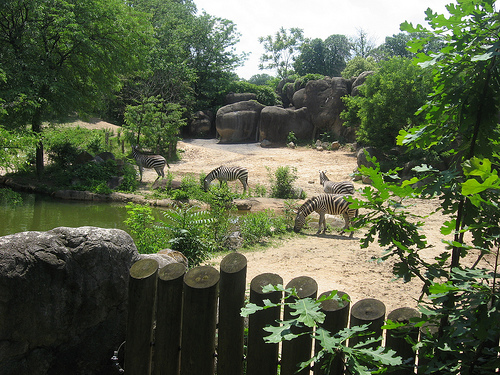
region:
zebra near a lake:
[277, 185, 357, 232]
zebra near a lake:
[310, 171, 340, 191]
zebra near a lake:
[196, 162, 257, 200]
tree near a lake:
[20, 70, 67, 161]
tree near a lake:
[128, 86, 182, 139]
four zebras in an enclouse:
[129, 136, 364, 238]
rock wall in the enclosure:
[185, 59, 375, 138]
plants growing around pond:
[13, 127, 276, 261]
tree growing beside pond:
[2, 32, 188, 172]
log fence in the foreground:
[135, 254, 476, 373]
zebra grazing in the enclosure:
[195, 159, 362, 232]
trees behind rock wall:
[196, 36, 413, 113]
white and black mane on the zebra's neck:
[294, 197, 312, 212]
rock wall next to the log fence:
[6, 222, 131, 359]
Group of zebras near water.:
[123, 146, 368, 249]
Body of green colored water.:
[9, 175, 326, 255]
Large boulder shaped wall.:
[222, 67, 358, 147]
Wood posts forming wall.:
[124, 241, 315, 373]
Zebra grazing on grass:
[284, 191, 371, 243]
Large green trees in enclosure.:
[1, 0, 235, 166]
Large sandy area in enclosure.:
[162, 120, 496, 315]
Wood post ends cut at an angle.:
[115, 233, 286, 333]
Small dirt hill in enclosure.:
[4, 68, 238, 184]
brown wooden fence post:
[121, 259, 154, 370]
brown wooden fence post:
[152, 263, 182, 373]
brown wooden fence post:
[180, 264, 215, 371]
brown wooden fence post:
[216, 251, 246, 373]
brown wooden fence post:
[241, 271, 281, 373]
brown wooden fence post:
[281, 274, 313, 374]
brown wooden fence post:
[315, 290, 343, 373]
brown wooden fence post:
[346, 298, 381, 374]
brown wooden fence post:
[383, 308, 417, 373]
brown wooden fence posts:
[125, 253, 417, 372]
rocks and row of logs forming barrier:
[5, 225, 486, 365]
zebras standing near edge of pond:
[4, 140, 361, 242]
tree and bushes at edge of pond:
[5, 4, 142, 214]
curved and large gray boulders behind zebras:
[211, 37, 361, 239]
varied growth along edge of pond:
[120, 191, 285, 256]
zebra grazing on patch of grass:
[283, 192, 360, 240]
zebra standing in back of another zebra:
[288, 164, 358, 237]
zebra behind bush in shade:
[108, 137, 170, 189]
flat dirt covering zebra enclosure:
[11, 120, 494, 305]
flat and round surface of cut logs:
[128, 249, 420, 334]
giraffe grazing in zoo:
[289, 190, 361, 237]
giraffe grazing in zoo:
[198, 161, 253, 206]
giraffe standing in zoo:
[126, 143, 171, 188]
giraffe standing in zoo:
[316, 168, 357, 228]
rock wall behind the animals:
[238, 99, 331, 143]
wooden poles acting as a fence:
[148, 271, 223, 341]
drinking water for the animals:
[40, 207, 74, 221]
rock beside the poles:
[60, 230, 92, 276]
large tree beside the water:
[4, 16, 126, 163]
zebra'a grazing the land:
[136, 146, 404, 237]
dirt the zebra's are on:
[322, 246, 358, 274]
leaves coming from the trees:
[343, 165, 449, 281]